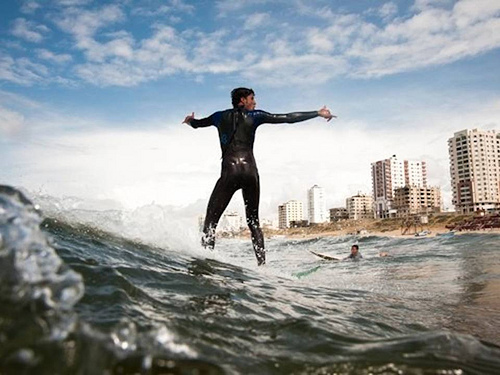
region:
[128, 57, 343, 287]
man is surfing in the ocean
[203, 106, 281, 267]
man has a black wet suit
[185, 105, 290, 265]
the wet suit is shiny and wet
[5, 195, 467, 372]
the water is dark in color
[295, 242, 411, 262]
man on a surfboard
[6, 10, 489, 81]
blue sky with clouds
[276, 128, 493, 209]
hotels on the beach front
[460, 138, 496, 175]
the hotels have windows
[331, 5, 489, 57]
the clouds are white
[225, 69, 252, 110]
the man has dark hair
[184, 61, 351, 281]
The man is surfing.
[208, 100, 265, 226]
The wetsuit is black.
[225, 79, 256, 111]
The man has brown hair.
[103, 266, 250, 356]
The water is grey.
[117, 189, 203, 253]
The water is white.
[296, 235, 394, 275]
Another person lying on a surfboard.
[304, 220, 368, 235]
The beach is brown.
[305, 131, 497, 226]
Buildings on the beach.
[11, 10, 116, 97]
The sky is blue.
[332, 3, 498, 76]
There are clouds in the sky.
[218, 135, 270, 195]
The wetsuit is black.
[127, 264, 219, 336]
The water is grey.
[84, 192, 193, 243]
The water is white.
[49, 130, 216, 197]
The sky is white.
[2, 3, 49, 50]
The sky is blue.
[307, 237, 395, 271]
Another man on a surfboard.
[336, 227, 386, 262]
The man is in the water.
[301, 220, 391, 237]
The beach is tan.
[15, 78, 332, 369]
a surfer catching a wave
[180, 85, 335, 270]
the surfer has a black wet suit on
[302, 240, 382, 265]
a surfer going out for a wave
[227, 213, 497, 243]
the waves are hitting a sandy beach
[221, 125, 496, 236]
tall buildings dot the beach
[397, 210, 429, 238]
a life guard stand is on the beach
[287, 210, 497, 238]
dunes are on the beach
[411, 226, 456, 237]
boats are on the beach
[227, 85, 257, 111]
the surfer has dark hair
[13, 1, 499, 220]
the sky is blue with puffy clouds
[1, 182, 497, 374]
water in the ocean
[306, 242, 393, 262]
person on belly on surfboard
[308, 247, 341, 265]
surfboard in the water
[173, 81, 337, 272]
man surfing on waves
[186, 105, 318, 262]
man's black colored wetsuit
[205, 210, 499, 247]
brown soil of the shore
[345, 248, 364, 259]
person's grey shirt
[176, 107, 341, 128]
surfer's outstretched arms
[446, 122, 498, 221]
tallest building on the beach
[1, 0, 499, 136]
blue portion of the sky